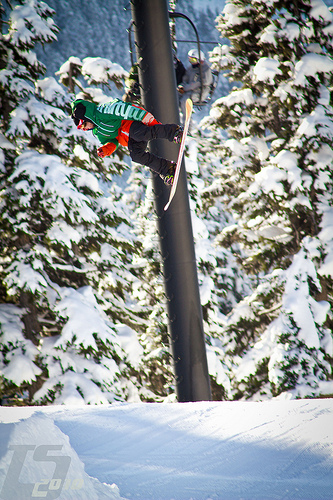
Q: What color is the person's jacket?
A: Green.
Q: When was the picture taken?
A: During the day.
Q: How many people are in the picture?
A: One.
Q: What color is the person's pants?
A: Black.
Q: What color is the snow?
A: White.